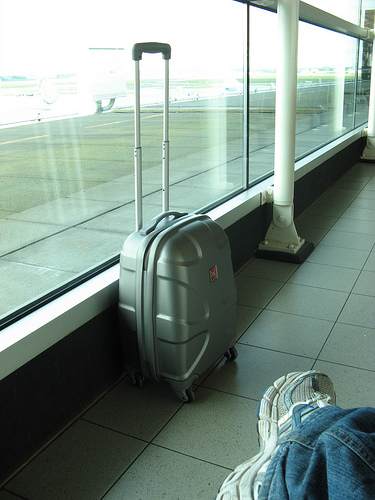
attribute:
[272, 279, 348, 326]
while tile — white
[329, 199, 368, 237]
while tile — white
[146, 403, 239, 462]
while tile — white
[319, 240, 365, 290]
while tile — white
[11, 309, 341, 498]
floor — white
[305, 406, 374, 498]
leg — human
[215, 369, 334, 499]
foot — human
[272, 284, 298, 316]
tile — white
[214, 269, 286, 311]
tile — white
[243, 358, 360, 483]
jean — blue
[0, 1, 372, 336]
windows — clear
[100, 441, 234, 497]
tile — white, square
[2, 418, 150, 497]
tile — square, white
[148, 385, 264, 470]
tile — square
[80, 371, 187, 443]
tile — square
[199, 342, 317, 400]
tile — square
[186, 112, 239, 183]
tile — white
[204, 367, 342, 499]
sneaker — white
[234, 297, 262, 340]
floor tile — white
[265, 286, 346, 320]
floor tile — white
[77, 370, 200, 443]
tile — white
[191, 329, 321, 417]
tile — white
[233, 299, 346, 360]
tile — white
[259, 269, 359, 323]
tile — white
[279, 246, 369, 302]
tile — white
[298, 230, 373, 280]
tile — white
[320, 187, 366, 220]
tile — white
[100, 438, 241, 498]
tile — white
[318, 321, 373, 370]
tile — white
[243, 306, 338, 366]
tile — white